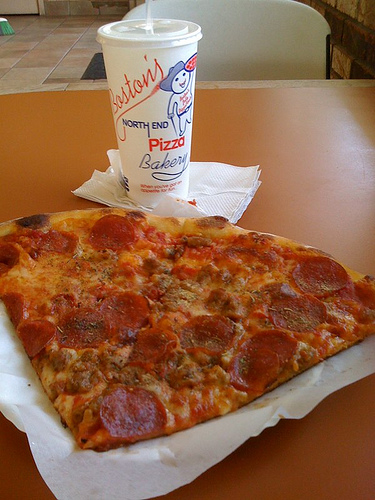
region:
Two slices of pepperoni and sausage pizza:
[0, 205, 372, 455]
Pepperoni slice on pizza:
[98, 378, 173, 439]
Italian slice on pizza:
[61, 360, 103, 396]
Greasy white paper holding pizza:
[3, 229, 373, 499]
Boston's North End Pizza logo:
[100, 64, 191, 154]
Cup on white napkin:
[84, 21, 259, 219]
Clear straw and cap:
[91, 4, 201, 51]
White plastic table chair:
[124, 1, 343, 75]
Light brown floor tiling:
[3, 19, 103, 87]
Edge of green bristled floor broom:
[0, 14, 16, 39]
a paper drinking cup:
[93, 19, 201, 206]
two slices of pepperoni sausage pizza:
[1, 210, 374, 449]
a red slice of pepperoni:
[100, 386, 164, 440]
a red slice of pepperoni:
[233, 345, 278, 391]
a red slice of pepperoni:
[251, 328, 296, 366]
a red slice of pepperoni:
[177, 313, 237, 356]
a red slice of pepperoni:
[119, 330, 177, 365]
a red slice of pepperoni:
[100, 292, 148, 333]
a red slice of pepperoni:
[60, 309, 108, 348]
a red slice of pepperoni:
[16, 318, 56, 356]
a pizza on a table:
[17, 196, 373, 446]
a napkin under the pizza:
[0, 288, 371, 495]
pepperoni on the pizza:
[5, 211, 357, 440]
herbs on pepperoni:
[274, 262, 340, 329]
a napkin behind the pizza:
[80, 131, 279, 231]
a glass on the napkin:
[94, 13, 196, 201]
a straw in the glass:
[140, 2, 153, 33]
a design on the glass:
[111, 50, 198, 190]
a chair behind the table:
[109, 2, 336, 94]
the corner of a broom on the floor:
[0, 10, 16, 38]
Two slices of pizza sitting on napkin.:
[0, 207, 373, 451]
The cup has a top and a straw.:
[95, 0, 224, 212]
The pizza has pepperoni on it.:
[1, 213, 373, 443]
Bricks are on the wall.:
[299, 0, 374, 80]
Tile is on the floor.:
[1, 13, 119, 90]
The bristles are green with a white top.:
[0, 16, 15, 36]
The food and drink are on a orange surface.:
[0, 77, 373, 497]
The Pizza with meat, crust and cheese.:
[0, 205, 373, 450]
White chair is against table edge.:
[119, 0, 332, 83]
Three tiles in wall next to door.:
[0, 0, 130, 17]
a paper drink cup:
[72, 19, 201, 256]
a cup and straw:
[111, 1, 199, 246]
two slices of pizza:
[1, 256, 327, 464]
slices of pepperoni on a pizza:
[225, 255, 350, 342]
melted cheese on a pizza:
[161, 269, 263, 365]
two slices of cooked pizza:
[0, 230, 355, 399]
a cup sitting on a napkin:
[58, 125, 262, 239]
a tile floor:
[25, 22, 78, 86]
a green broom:
[0, 6, 25, 33]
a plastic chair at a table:
[95, 14, 340, 89]